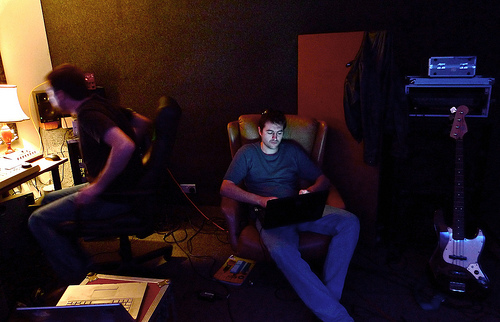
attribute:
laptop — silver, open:
[27, 274, 129, 319]